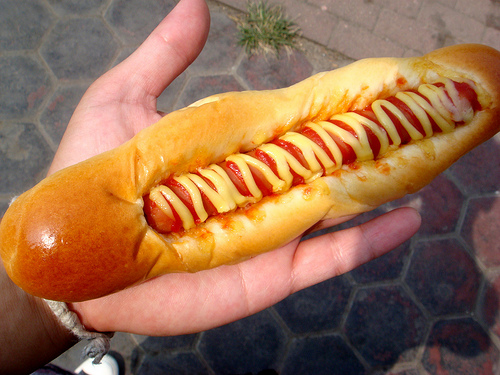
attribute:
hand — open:
[83, 42, 149, 139]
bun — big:
[29, 186, 157, 279]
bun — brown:
[5, 190, 143, 283]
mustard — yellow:
[204, 174, 234, 204]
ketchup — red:
[274, 136, 292, 151]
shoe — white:
[82, 354, 109, 373]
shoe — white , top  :
[67, 351, 125, 371]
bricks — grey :
[315, 11, 414, 42]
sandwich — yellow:
[1, 30, 483, 310]